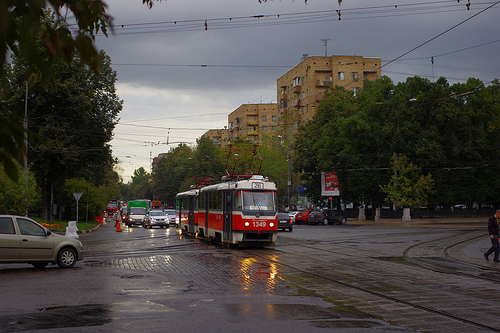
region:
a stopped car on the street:
[0, 210, 88, 268]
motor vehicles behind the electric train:
[117, 205, 172, 227]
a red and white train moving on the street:
[171, 170, 276, 245]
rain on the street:
[105, 250, 466, 326]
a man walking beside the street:
[480, 206, 496, 261]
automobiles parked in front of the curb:
[292, 205, 347, 225]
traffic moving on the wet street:
[111, 171, 291, 246]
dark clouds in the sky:
[117, 0, 272, 95]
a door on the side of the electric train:
[217, 190, 233, 243]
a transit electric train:
[173, 139, 280, 250]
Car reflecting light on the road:
[167, 254, 170, 261]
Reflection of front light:
[271, 260, 276, 275]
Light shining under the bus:
[195, 231, 198, 236]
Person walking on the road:
[481, 207, 497, 262]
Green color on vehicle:
[133, 200, 144, 203]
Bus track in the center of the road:
[282, 263, 285, 265]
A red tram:
[172, 169, 284, 251]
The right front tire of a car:
[55, 242, 82, 271]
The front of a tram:
[233, 172, 283, 249]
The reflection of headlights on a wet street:
[234, 250, 287, 318]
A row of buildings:
[152, 48, 390, 164]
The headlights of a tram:
[240, 217, 277, 232]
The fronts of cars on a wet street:
[112, 198, 182, 238]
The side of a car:
[2, 212, 89, 272]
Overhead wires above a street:
[61, 0, 498, 164]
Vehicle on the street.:
[194, 158, 285, 250]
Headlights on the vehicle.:
[237, 216, 279, 233]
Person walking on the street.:
[480, 203, 498, 265]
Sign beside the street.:
[67, 186, 84, 221]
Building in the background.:
[271, 47, 388, 187]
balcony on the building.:
[287, 74, 305, 94]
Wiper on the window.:
[247, 188, 268, 219]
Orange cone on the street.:
[112, 217, 126, 234]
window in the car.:
[14, 215, 49, 242]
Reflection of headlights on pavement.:
[233, 250, 286, 294]